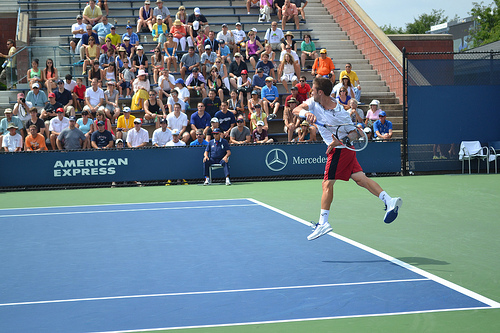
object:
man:
[285, 74, 400, 239]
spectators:
[78, 39, 98, 59]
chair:
[457, 138, 484, 172]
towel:
[457, 140, 485, 159]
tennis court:
[4, 195, 490, 332]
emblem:
[259, 145, 295, 182]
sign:
[250, 148, 305, 176]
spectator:
[186, 104, 213, 134]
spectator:
[246, 85, 268, 117]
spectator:
[229, 51, 248, 79]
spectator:
[115, 46, 128, 70]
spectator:
[290, 71, 310, 104]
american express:
[51, 155, 128, 177]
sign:
[31, 156, 144, 179]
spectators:
[26, 56, 45, 77]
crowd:
[19, 8, 374, 130]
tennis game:
[0, 0, 500, 333]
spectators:
[81, 79, 105, 110]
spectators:
[243, 100, 278, 125]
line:
[4, 281, 342, 303]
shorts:
[320, 146, 365, 183]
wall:
[382, 43, 459, 148]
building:
[299, 8, 494, 190]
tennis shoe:
[379, 195, 406, 222]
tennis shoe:
[305, 220, 330, 245]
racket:
[318, 118, 371, 151]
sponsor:
[38, 148, 156, 194]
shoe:
[302, 216, 337, 244]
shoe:
[374, 190, 404, 230]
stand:
[29, 13, 369, 126]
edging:
[95, 141, 496, 247]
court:
[0, 172, 500, 330]